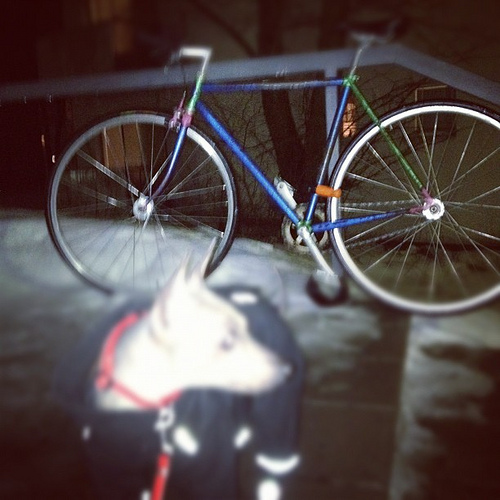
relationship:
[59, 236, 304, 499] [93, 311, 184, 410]
dog has collar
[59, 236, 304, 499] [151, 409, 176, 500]
dog has leash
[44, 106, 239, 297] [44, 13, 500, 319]
front tire on bicycle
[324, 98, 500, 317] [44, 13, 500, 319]
rear tire on bicycle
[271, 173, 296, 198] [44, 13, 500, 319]
pedal on bicycle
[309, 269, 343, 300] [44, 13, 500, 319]
pedal on bicycle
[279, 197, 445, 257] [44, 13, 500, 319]
chain on bicycle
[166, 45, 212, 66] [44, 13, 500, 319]
handlebars on bicycle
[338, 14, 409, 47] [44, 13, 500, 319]
seat on bicycle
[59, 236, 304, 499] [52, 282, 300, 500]
dog wearing clothes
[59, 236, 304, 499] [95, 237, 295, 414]
dog has hair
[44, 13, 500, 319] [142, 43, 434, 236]
bicycle has frame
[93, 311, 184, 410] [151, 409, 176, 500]
collar has leash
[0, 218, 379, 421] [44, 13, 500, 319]
snow under bicycle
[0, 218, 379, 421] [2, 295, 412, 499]
snow on porch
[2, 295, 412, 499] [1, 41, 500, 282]
porch has railing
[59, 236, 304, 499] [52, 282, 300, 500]
dog has clothes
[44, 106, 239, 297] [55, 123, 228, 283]
tire has spokes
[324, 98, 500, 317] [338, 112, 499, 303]
tire has spokes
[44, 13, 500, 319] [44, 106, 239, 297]
bicycle has tire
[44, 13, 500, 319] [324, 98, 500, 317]
bicycle has tire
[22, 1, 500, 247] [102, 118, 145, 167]
house has window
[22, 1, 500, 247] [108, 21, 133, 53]
house has window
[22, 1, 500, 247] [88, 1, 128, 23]
house has window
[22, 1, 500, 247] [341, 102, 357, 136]
house has window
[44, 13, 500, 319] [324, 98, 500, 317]
bicycle has rear tire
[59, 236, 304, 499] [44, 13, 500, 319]
dog in front of bicycle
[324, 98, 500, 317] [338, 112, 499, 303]
rear tire has spokes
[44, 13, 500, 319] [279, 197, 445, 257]
bicycle has chain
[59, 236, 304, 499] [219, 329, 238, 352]
dog has eye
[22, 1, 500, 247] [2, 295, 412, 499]
house behind porch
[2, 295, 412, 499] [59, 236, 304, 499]
porch under dog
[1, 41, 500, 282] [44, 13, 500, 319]
railing behind bicycle